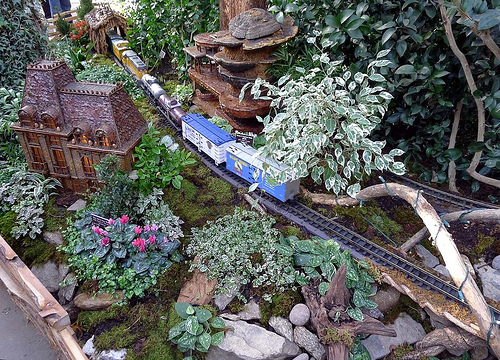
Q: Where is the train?
A: On the tracks.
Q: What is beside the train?
A: A building.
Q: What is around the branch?
A: Lights.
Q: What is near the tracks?
A: Flowers.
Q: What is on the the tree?
A: Fungus.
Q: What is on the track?
A: A train.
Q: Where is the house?
A: Near the tracks.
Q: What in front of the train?
A: Tracks.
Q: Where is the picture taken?
A: A garden.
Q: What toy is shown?
A: Train.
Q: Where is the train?
A: Tracks.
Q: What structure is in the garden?
A: A house.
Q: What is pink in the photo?
A: Flowers.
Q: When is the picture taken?
A: Afternoon.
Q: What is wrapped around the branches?
A: Fairy lights.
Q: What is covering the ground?
A: Moss.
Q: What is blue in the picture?
A: Train.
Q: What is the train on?
A: A black train track.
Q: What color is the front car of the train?
A: Blue.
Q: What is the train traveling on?
A: Tracks.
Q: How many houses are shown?
A: One.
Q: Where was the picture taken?
A: A miniature train exhibit.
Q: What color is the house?
A: Brown.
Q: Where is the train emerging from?
A: A tunnel.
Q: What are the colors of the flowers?
A: Pink.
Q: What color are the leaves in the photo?
A: Green.